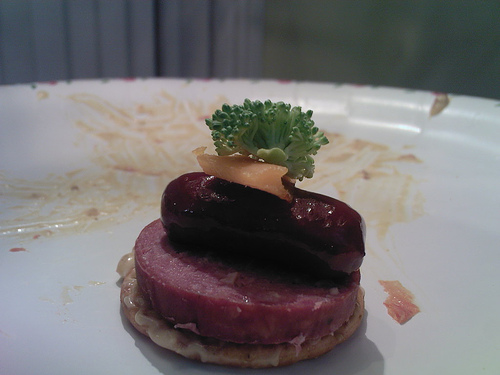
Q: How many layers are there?
A: Five.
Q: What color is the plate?
A: White.